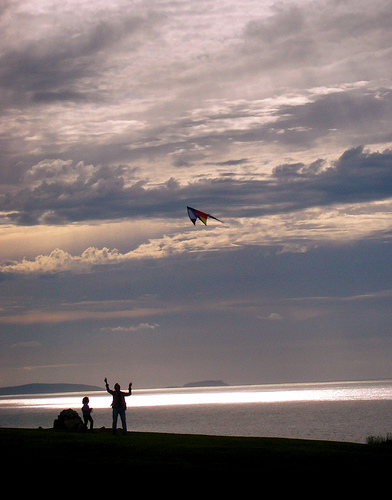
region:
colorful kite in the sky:
[177, 193, 231, 242]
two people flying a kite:
[65, 355, 140, 446]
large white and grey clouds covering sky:
[27, 234, 161, 315]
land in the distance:
[10, 368, 104, 403]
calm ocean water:
[235, 380, 346, 432]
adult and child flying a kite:
[61, 363, 142, 441]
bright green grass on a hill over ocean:
[112, 422, 266, 464]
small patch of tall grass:
[361, 429, 390, 450]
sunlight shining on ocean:
[192, 369, 352, 420]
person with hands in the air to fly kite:
[101, 368, 146, 439]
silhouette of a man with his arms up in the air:
[99, 370, 138, 432]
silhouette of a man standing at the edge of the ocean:
[101, 374, 138, 435]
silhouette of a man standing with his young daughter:
[102, 374, 133, 433]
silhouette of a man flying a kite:
[102, 371, 135, 430]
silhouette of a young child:
[80, 391, 95, 434]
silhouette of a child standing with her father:
[74, 388, 98, 428]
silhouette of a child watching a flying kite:
[77, 390, 96, 430]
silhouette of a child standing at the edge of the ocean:
[79, 391, 95, 430]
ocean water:
[200, 387, 334, 423]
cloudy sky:
[110, 248, 320, 331]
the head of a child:
[79, 392, 93, 406]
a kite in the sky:
[180, 198, 224, 234]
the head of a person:
[112, 378, 125, 392]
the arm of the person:
[121, 377, 135, 397]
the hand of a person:
[124, 378, 135, 388]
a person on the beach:
[93, 369, 140, 440]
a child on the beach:
[76, 390, 95, 433]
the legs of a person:
[109, 409, 130, 433]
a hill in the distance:
[1, 375, 110, 404]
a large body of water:
[1, 376, 390, 445]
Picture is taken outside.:
[68, 46, 321, 374]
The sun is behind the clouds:
[65, 173, 350, 407]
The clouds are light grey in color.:
[64, 170, 330, 355]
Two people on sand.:
[46, 374, 191, 450]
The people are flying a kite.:
[29, 178, 281, 479]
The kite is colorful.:
[156, 172, 275, 276]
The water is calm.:
[213, 402, 316, 440]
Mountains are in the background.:
[24, 374, 271, 394]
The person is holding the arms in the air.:
[100, 346, 162, 432]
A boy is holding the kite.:
[64, 340, 113, 459]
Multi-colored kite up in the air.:
[178, 198, 228, 242]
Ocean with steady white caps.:
[157, 380, 376, 432]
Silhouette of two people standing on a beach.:
[76, 371, 141, 434]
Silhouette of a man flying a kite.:
[98, 369, 141, 432]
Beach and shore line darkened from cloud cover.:
[136, 430, 360, 480]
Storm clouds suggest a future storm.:
[2, 147, 382, 226]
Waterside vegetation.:
[356, 425, 390, 452]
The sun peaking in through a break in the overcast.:
[19, 388, 370, 409]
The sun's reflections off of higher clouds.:
[2, 217, 194, 265]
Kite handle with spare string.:
[100, 367, 115, 383]